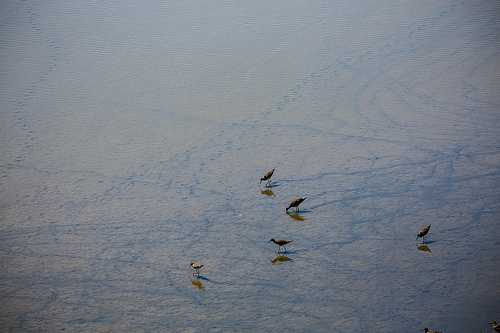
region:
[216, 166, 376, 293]
Bird walking in the water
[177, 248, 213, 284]
Bird walking in the water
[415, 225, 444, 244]
Bird walking in the water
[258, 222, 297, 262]
Bird walking in the water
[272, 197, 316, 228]
Bird walking in the water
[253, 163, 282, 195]
Bird walking in the water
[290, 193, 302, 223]
Bird walking in the water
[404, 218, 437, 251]
Bird walking in the water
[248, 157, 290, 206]
Bird walking in the water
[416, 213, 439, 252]
brown bird on wet sand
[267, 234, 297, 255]
brown bird on wet sand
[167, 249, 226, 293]
brown bird on wet sand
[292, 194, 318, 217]
brown bird on wet sand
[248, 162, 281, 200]
brown bird on wet sand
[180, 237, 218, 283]
brown bird on wet sand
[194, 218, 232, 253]
brown bird on wet sand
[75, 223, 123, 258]
brown bird on wet sand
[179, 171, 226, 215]
brown bird on wet sand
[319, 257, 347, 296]
brown bird on wet sand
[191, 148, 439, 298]
A small flock of birds in a body of water.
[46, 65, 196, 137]
a section of a body of water.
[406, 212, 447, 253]
a small bird in water.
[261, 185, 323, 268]
a couple of small birds.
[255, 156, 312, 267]
a small flock of birds.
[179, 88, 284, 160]
a crack in the floor of a river.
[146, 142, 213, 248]
lines on a river bottom.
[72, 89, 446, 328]
a flock of birds looking for food.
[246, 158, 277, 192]
a bird in a body of clear water.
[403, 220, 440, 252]
a bird with feathers.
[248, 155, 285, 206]
bird standing on ice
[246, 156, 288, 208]
bird standing and pecking at ice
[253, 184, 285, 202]
black shadow of bird on ice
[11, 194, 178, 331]
patch of iced surface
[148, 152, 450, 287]
group of small birds standing on ice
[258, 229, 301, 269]
bird walking across ice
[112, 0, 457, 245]
long diagonal trail across ice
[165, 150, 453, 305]
five birds facing the left on ice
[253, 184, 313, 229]
two black shadows of birds on ice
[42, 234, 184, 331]
dark lines on top of iced over surface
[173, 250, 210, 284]
birds on the water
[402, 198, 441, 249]
birds on the water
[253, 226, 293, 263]
birds on the water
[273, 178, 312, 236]
birds on the water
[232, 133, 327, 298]
birds on the water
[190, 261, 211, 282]
the bird is brown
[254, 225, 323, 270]
the bird is brown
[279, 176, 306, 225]
the bird is brown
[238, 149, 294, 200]
the bird is brown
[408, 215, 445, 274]
the bird is brown